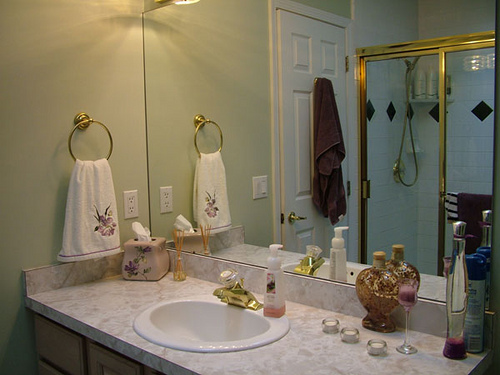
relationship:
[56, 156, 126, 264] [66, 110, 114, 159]
hand towel on a bronze holder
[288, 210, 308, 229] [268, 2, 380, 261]
door handle on a white door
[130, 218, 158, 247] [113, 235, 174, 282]
paper in dispenser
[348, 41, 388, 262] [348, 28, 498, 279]
frame on shower door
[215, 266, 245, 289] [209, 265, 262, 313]
handle on bathroom faucet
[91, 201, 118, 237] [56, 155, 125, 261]
flower on towel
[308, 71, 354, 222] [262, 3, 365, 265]
towel hanging on door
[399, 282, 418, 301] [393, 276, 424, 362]
candle in glass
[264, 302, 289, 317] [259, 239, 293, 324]
soap in bottle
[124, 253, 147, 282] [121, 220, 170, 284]
flower on kleenex box